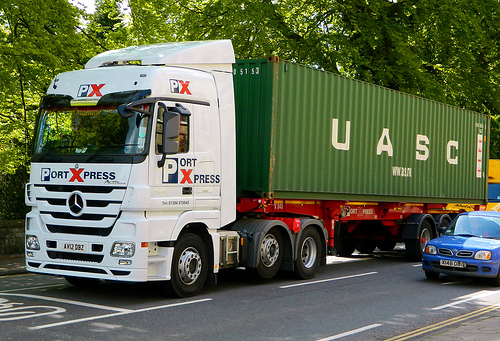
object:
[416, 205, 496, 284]
sabb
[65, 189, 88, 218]
emblen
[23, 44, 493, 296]
truck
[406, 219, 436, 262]
tire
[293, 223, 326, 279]
tire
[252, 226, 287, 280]
tire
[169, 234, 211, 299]
tire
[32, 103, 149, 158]
window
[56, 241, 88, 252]
plate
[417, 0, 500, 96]
tree branch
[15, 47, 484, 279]
truck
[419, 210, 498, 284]
car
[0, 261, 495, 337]
road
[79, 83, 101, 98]
letters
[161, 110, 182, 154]
mirror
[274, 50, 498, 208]
trailer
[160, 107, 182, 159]
side mirror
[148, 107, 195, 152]
sidemirror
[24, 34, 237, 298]
cab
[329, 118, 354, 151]
logo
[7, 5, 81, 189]
tree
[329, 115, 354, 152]
u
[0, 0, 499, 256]
trees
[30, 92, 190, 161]
windshield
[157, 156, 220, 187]
port xpress